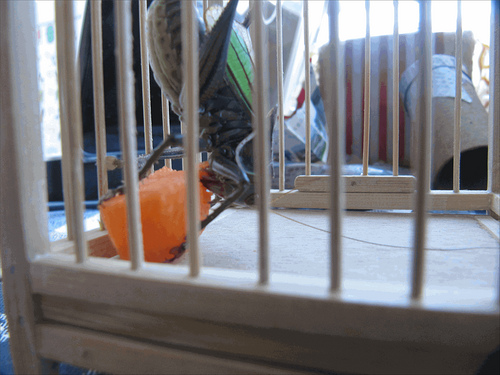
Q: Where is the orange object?
A: In the white crib.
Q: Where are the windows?
A: Behind the crib.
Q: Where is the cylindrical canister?
A: Behind the crib.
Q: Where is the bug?
A: In the crib.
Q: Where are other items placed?
A: Behind the crib.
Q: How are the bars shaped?
A: Round.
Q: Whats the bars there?
A: Cage.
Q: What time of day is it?
A: Afternoon.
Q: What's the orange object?
A: Bag.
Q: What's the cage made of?
A: Metal.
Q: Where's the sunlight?
A: Shining through window.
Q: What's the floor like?
A: Carpet.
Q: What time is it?
A: 12:45PM.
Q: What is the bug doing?
A: Eating fruit.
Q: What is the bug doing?
A: Holding fruit.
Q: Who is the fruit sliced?
A: In a cube.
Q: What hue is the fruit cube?
A: Orange.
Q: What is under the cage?
A: A blue floor.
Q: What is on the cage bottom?
A: Fruit.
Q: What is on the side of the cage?
A: Brown wooden bars.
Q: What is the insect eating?
A: Fruit.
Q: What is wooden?
A: Rods.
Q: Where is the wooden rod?
A: A box.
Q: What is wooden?
A: A box.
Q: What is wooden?
A: Rod.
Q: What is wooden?
A: Rods.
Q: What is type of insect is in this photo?
A: A grasshopper.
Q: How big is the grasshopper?
A: Four inches.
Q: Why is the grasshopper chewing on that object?
A: It's eating it.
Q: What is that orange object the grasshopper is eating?
A: A piece of carrot.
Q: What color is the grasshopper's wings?
A: Green.